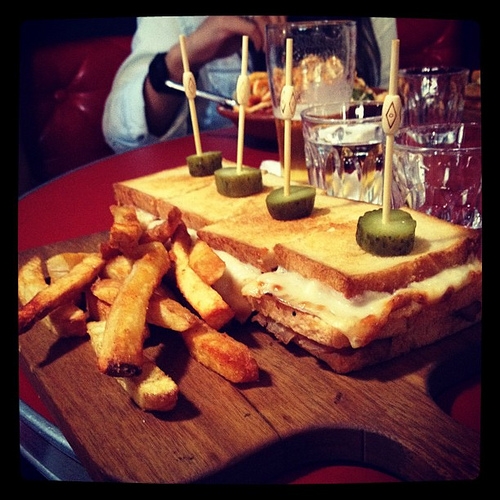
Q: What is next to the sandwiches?
A: Fries.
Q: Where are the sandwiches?
A: Board.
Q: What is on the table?
A: The glass cups.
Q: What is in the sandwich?
A: Melted cheese.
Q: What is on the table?
A: Wooden board.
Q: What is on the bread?
A: Pickles.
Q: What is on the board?
A: Fries.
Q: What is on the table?
A: The cutting board.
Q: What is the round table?
A: Red.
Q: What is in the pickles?
A: The sticks.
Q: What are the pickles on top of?
A: Sandwiches.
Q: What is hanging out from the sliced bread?
A: Cheese.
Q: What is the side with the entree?
A: French fries.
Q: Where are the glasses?
A: Behind the sandwiches.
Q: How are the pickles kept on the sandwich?
A: Skewers.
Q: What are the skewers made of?
A: Wood.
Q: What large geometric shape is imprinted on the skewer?
A: Diamond.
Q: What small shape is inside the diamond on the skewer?
A: Circle.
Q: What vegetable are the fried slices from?
A: Potato.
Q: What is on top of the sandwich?
A: Four pickles on toothpicks.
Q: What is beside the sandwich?
A: French fries.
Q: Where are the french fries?
A: Beside the sandwich.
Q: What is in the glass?
A: Water.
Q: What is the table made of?
A: Wood painted red.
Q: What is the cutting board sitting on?
A: A table.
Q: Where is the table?
A: Under the cutting board.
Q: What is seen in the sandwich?
A: Melted cheese.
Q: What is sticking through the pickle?
A: A skewer.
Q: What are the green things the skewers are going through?
A: Pickles.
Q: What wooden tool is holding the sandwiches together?
A: Skewers.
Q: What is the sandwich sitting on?
A: A cutting board.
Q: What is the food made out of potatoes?
A: Fries.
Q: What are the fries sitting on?
A: A cutting board.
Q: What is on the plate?
A: Sandwiches and fries.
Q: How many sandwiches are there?
A: Four.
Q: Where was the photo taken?
A: In a restaurant.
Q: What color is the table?
A: Red.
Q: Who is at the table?
A: The person who going to eat the food.